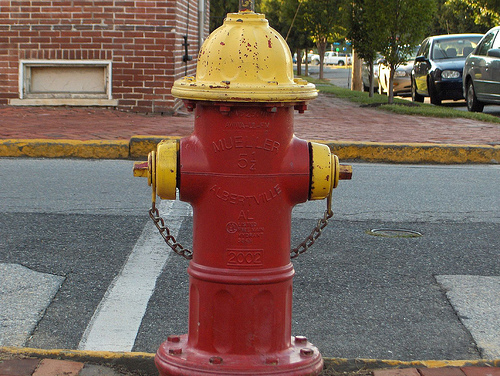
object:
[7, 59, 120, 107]
casement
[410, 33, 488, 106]
cars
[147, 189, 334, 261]
chains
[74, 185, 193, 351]
markings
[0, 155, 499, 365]
road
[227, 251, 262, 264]
"2002"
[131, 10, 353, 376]
fire hydrant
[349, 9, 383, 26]
leaves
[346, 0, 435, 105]
tree